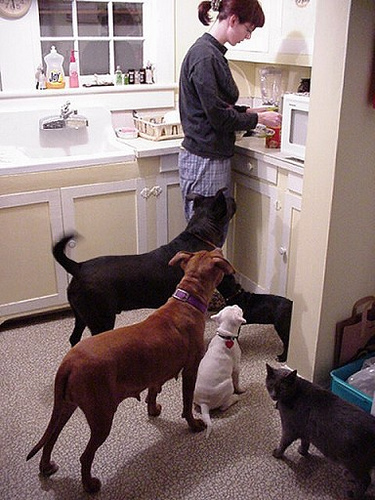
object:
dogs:
[204, 267, 293, 361]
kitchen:
[0, 1, 375, 499]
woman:
[178, 0, 284, 313]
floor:
[0, 283, 375, 498]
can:
[264, 125, 280, 147]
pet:
[190, 304, 247, 439]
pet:
[52, 188, 237, 349]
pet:
[24, 248, 238, 493]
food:
[263, 125, 281, 149]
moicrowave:
[279, 92, 311, 158]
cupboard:
[271, 1, 314, 61]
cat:
[265, 363, 373, 498]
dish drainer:
[131, 111, 179, 141]